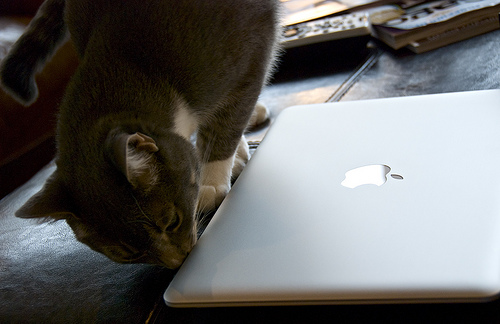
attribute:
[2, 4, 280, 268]
cat — grey, white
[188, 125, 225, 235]
whiskers — white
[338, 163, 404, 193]
logo — apple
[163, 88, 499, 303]
laptop — closed, silver, grey, computer, apple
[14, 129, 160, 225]
ears — white, grey, hairy, furry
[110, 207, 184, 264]
eyes — green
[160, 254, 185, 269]
nose — gray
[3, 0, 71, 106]
tail — grey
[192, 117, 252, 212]
paws — white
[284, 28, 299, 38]
button — orange